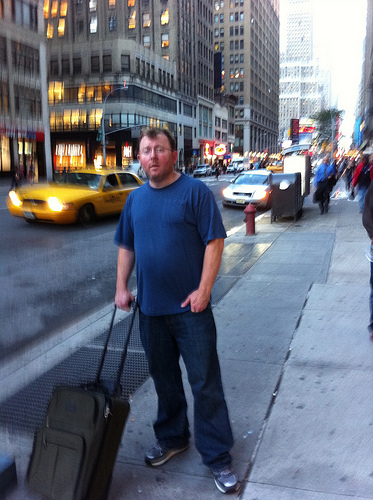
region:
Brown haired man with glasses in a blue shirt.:
[114, 127, 238, 494]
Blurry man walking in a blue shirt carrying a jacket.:
[313, 155, 337, 214]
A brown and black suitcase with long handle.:
[26, 298, 137, 498]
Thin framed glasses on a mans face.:
[137, 147, 172, 155]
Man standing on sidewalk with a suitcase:
[24, 126, 237, 499]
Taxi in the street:
[4, 167, 145, 228]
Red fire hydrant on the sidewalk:
[241, 203, 257, 236]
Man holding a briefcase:
[311, 153, 335, 216]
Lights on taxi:
[8, 189, 74, 209]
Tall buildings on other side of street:
[0, 0, 329, 176]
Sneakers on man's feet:
[143, 437, 237, 495]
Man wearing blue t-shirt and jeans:
[113, 126, 239, 491]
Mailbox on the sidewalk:
[268, 172, 304, 223]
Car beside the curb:
[221, 167, 276, 215]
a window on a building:
[68, 56, 83, 81]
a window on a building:
[52, 84, 63, 102]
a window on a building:
[92, 150, 107, 167]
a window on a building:
[121, 50, 130, 72]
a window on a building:
[161, 31, 168, 49]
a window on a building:
[159, 10, 171, 29]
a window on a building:
[140, 12, 151, 29]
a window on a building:
[105, 12, 118, 31]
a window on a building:
[56, 16, 66, 42]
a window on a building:
[160, 32, 169, 50]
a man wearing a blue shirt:
[110, 126, 243, 494]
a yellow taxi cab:
[6, 160, 139, 228]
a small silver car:
[220, 162, 275, 208]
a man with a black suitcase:
[24, 120, 240, 498]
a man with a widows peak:
[110, 125, 238, 491]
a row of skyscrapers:
[0, 0, 329, 132]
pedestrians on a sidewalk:
[314, 150, 371, 213]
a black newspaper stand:
[268, 171, 302, 222]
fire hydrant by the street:
[238, 201, 264, 238]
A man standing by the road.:
[32, 131, 266, 497]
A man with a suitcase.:
[42, 124, 229, 493]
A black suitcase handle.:
[91, 287, 143, 391]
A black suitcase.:
[32, 372, 126, 497]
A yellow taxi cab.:
[10, 150, 155, 241]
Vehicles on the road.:
[10, 148, 325, 373]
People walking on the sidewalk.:
[11, 113, 370, 495]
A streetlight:
[93, 82, 145, 170]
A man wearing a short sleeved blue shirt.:
[106, 117, 240, 478]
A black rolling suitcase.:
[20, 295, 144, 498]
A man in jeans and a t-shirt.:
[112, 125, 243, 494]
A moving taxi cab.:
[4, 161, 146, 228]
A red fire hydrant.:
[241, 203, 258, 237]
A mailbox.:
[264, 170, 301, 224]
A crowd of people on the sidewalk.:
[312, 149, 371, 215]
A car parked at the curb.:
[219, 167, 278, 212]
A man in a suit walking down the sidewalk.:
[311, 155, 338, 216]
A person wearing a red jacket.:
[347, 154, 371, 214]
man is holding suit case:
[113, 126, 241, 495]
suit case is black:
[25, 299, 137, 498]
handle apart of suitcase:
[93, 298, 139, 392]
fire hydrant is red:
[243, 202, 256, 232]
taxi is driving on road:
[5, 170, 146, 227]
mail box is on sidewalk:
[268, 171, 301, 222]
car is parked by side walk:
[221, 170, 279, 212]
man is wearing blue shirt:
[313, 153, 335, 215]